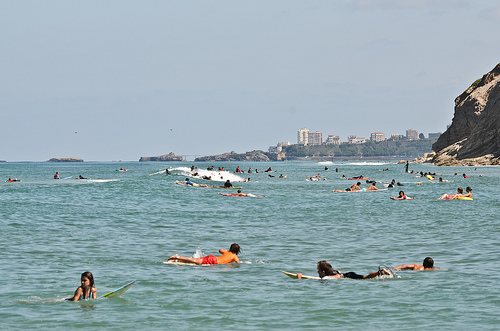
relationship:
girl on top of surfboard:
[63, 270, 99, 301] [96, 279, 141, 307]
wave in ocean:
[315, 159, 335, 166] [0, 159, 497, 330]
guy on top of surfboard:
[294, 256, 403, 283] [279, 269, 323, 280]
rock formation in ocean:
[43, 155, 85, 165] [0, 159, 497, 330]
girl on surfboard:
[63, 270, 99, 301] [96, 279, 141, 307]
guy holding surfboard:
[294, 256, 403, 283] [279, 269, 323, 280]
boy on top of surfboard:
[167, 242, 246, 269] [161, 259, 255, 270]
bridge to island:
[177, 152, 205, 164] [138, 149, 186, 164]